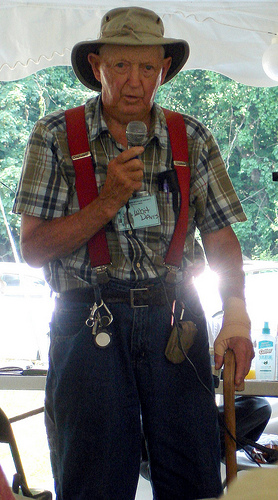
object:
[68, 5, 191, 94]
green hat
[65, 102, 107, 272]
red suspender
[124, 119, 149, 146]
microphone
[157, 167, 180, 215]
glasses case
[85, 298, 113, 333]
key ring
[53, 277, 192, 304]
black belt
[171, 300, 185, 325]
case handing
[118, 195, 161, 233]
name tag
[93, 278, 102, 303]
clips on a belt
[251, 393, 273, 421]
knee of man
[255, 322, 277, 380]
squeeze bottle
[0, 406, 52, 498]
chair sitting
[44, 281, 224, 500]
blue jeans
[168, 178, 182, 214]
pen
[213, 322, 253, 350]
bandage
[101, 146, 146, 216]
hand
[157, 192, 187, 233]
pocket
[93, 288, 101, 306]
belt loop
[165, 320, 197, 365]
case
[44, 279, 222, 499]
pants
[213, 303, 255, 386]
hand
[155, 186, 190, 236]
pocket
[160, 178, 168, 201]
pen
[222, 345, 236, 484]
cane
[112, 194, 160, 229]
tag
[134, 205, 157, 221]
writing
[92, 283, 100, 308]
hoop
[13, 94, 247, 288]
shirt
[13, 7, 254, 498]
man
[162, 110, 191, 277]
suspenders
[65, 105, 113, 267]
suspenders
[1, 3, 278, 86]
tent